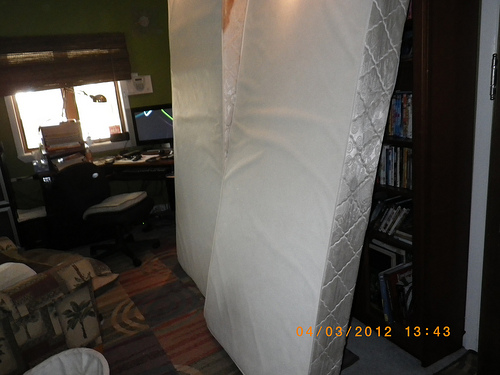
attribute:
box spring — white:
[202, 1, 411, 375]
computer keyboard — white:
[114, 154, 158, 163]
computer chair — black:
[56, 160, 163, 268]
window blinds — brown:
[1, 32, 134, 90]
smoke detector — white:
[137, 11, 151, 29]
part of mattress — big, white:
[163, 1, 225, 297]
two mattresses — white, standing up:
[165, 0, 413, 375]